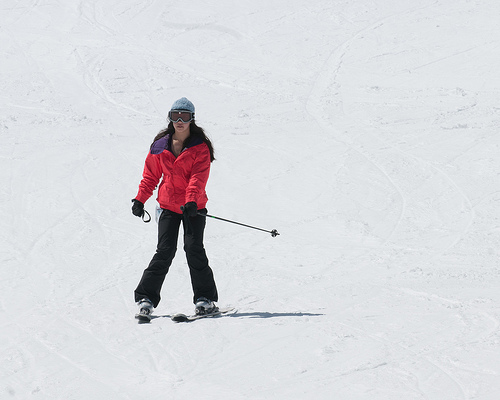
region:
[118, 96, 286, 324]
female on a pair of skis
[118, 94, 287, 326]
female skier on snow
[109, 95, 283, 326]
female skier wearing a beanie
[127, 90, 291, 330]
female skier holding ski poles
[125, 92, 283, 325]
skier wearing a beanie and pink coat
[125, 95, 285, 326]
female skier wearing goggles over her eyes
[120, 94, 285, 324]
lone female skier on snow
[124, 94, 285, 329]
female skier wearing pink and black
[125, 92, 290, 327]
woman all alone on skis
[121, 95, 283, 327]
female skiing with on ski in the air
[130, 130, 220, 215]
pink jacket on female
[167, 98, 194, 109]
blue beanie on woman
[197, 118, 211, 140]
long hair of woman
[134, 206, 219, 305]
black pants on woman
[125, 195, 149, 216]
black glove on woman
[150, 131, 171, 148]
purple inside of jacket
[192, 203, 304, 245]
black ski pole in hand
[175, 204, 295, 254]
hand holding black ski pole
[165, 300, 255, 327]
white ski on the ground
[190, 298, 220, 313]
white ski shoe on foot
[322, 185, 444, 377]
ground covered in snow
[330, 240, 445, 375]
ground covered in white snow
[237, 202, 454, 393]
snow covering the ground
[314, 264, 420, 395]
white snow covering the ground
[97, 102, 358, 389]
a woman that is skiing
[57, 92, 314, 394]
a woman on skis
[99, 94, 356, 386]
a woman holding ski poles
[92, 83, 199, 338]
a woma nwearin ga jacket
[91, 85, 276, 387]
a woman wearing pants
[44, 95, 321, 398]
a woman skiing on the snow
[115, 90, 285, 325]
woman on skiis going down a slope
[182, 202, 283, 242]
skii pole on the woman's left hand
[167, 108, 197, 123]
skii goggles on the woman's face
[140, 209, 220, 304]
the woman is wearing black pants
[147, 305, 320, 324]
shadow on the ground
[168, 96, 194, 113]
blue cap on the woman's head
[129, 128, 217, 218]
the woman is wearing a red jacket with a purple hood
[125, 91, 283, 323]
skiier going down a slope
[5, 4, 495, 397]
fresh snow on the slope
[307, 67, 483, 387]
skii track marks seen in the snow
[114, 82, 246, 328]
woman wears red coat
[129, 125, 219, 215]
red coat is black inside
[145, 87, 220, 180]
girl wears a beanie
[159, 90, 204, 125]
beanie is color blue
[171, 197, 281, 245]
snow pole on left hand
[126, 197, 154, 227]
strap of snow pole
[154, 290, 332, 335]
shadow cast on the snow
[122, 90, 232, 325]
woman has black pants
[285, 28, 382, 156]
mark of skis on snow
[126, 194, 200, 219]
gloves are color black